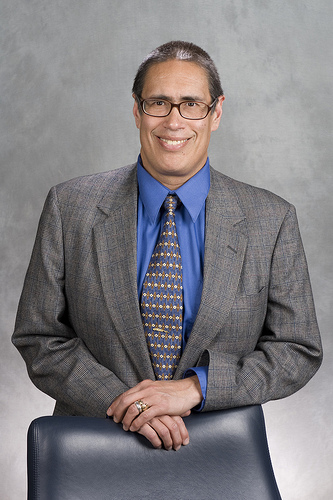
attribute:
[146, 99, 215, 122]
glasses — brown-rimmed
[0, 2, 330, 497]
wall — gray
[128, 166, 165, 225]
collar —  on left 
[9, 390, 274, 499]
chair — dark blue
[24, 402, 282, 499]
chair — blue, leather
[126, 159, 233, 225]
collar — blue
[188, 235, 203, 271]
shirt — blue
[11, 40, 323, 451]
man — smiling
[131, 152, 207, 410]
shirt — blue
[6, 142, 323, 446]
blazer — gray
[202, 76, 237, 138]
ear — large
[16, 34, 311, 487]
man — blue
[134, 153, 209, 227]
collar — blue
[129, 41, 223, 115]
hair — dark brown, short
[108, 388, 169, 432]
rings — metal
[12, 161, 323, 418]
suit — grey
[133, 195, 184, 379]
tie — gold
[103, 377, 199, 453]
hands — clasped